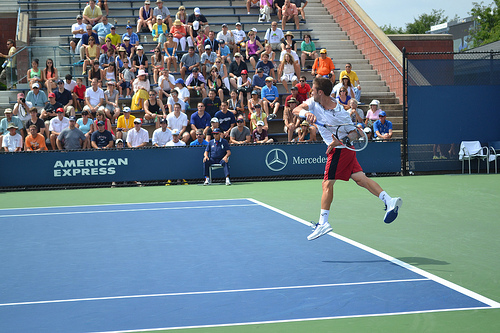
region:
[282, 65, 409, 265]
man playing tennis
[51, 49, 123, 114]
observant spectators sitting in stand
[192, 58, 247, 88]
observant spectators sitting in stand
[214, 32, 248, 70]
observant spectators sitting in stand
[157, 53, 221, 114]
observant spectators sitting in stand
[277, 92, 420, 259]
man playing tennis on court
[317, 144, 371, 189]
red and black shorts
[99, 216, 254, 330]
blue and white tennis court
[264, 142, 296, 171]
mercedes emblem on sign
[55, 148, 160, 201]
american express on sign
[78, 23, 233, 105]
crowd watching tennis game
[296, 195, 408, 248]
white tennis shoes worn by man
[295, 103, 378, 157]
tennis racket held by man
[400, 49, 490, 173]
blue and black fence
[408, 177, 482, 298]
green edging of court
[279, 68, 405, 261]
Tennis player is in the air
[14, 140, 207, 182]
American Express is a sponsor of the tennis event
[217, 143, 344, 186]
Mercedes Benz is a sponsor of the tennis event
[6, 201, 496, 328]
The concrete court is painted in blue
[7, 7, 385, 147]
Spectators are watching the tennis match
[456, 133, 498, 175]
Empty chair has towel draped over the back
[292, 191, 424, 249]
Tennis player is wearing white tennis shoes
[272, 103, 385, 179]
Tennis player swing racket at the ball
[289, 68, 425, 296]
Tennis player is over the white line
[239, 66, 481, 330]
Tennis player is concentrating on the ball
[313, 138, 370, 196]
the shorts are red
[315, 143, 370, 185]
the shorts are red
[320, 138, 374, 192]
the shorts are red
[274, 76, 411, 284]
player is playing tennis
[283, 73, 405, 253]
player is playing tennis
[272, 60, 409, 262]
player is playing tennis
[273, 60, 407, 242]
player is playing tennis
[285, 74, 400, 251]
player is playing tennis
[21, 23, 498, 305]
this is a tennis court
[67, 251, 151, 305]
the line is white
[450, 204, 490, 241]
the court is green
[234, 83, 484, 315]
this is a player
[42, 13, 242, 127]
these are spectators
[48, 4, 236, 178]
the group is in the bleachers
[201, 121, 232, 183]
a person in a distance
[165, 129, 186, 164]
a person in a distance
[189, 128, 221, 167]
a person in a distance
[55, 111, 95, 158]
a person in a distance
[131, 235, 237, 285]
tennis court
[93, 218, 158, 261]
tennis court is blue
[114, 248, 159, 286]
a blue tennis court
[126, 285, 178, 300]
white line on the court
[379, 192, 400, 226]
a shoe